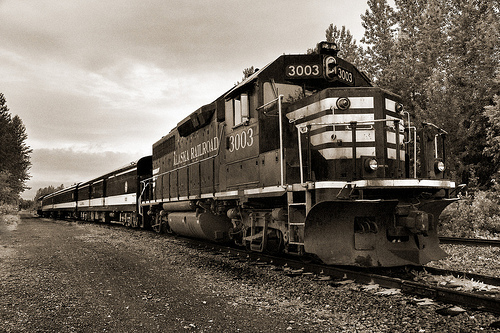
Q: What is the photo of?
A: A train.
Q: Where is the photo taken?
A: At a train track.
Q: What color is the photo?
A: Sepia.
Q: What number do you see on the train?
A: 3003.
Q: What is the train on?
A: On a rail track.